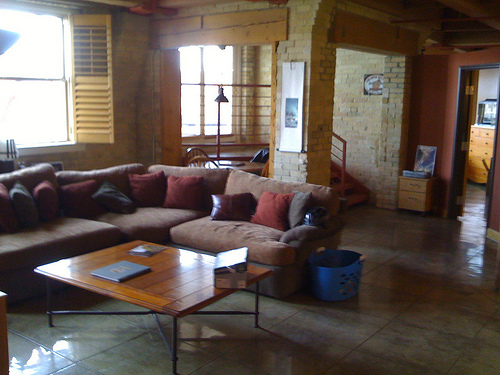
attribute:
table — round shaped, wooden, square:
[39, 236, 276, 373]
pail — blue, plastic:
[302, 240, 370, 309]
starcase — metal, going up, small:
[182, 79, 382, 211]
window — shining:
[1, 5, 92, 150]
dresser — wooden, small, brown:
[397, 168, 435, 216]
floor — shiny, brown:
[1, 186, 499, 369]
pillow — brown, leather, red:
[209, 186, 256, 223]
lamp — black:
[209, 86, 235, 170]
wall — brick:
[0, 3, 411, 217]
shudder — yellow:
[67, 12, 113, 145]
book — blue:
[90, 257, 153, 284]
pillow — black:
[95, 180, 140, 213]